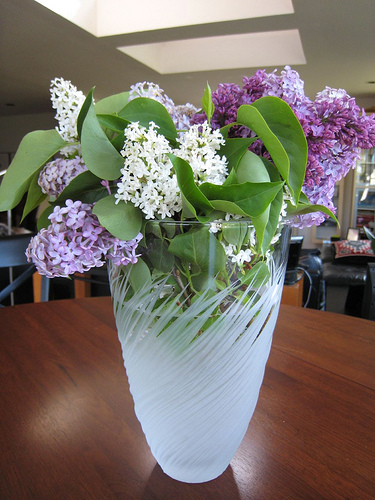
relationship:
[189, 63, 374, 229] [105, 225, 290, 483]
flowers on side of flower pot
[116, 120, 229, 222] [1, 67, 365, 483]
flowers in middle of flower pot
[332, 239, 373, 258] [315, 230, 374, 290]
pillow on couch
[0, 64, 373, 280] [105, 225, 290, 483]
flowers in flower pot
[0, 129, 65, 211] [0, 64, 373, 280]
leaf in flowers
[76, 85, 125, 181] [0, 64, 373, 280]
leaf in flowers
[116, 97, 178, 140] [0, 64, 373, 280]
leaf in flowers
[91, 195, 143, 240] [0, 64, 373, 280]
leaf in flowers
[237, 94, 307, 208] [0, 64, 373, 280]
leaf in flowers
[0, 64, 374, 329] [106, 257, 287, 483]
flowers in vase